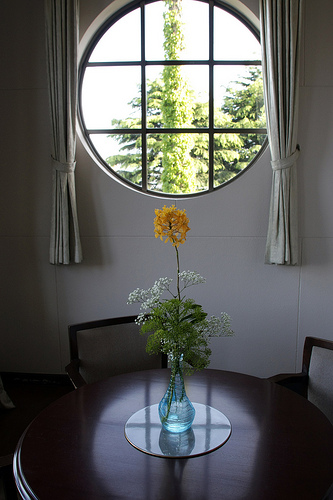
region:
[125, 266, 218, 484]
a flower vase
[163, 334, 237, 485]
a flower vase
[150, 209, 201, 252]
yellow bloom on flower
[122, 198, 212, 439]
blue vase of flowers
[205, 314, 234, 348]
white baby's breath in vase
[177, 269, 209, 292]
white baby's breath in vase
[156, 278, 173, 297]
white baby's breath in vase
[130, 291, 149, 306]
white baby's breath in vase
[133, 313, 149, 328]
white baby's breath in vase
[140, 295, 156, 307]
white baby's breath in vase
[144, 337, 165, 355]
green filler in vase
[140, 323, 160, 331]
green filler in vase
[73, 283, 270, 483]
the table is wooden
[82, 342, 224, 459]
the table is wooden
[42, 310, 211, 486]
the table is wooden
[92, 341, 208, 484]
the table is wooden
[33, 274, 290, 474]
the table is wooden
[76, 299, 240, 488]
the table is wooden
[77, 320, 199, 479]
the table is wooden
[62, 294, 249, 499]
the table is wooden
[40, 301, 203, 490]
the table is wooden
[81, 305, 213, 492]
the table is wooden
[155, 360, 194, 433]
a clear blue flower vase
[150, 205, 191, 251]
a tall yellow flower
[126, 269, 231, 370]
a bunch of baby's breath flowers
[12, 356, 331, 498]
a round dark brown table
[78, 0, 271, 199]
a round paned window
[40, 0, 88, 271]
a bunched grey curtain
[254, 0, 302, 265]
a bunched grey curtain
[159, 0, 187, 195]
at tall green tree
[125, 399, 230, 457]
a round mirror plate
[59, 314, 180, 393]
a dark wood chair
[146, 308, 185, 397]
a flower case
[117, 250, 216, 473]
a flower case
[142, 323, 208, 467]
a flower case